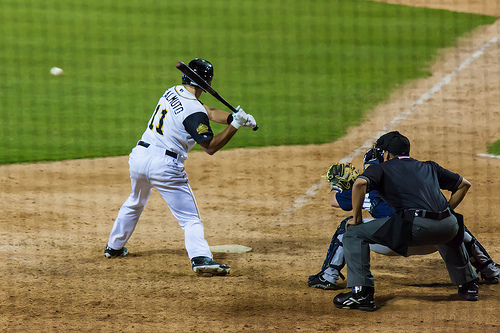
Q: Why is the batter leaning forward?
A: To hit the ball.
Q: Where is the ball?
A: Coming towards the batter.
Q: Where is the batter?
A: At home plate.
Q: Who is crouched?
A: The catcher and the umpire.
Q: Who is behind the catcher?
A: The umpire.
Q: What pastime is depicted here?
A: Baseball.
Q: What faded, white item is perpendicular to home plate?
A: A line.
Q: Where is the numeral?
A: On the back of the player's jersey.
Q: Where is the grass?
A: On the outfield.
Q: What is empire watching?
A: Pitch.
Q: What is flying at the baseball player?
A: A baseball.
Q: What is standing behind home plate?
A: A catcher.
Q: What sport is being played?
A: Baseball.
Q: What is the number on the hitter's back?
A: 11.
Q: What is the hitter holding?
A: A baseball bat.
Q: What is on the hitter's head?
A: A baseball helmet.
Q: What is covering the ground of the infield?
A: Grass.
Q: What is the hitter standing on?
A: Dirt.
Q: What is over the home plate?
A: The hitter.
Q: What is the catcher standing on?
A: Dirt.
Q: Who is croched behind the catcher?
A: The umpire.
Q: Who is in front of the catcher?
A: The batter.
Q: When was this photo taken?
A: During the day.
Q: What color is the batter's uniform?
A: White.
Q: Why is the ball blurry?
A: It is in motion.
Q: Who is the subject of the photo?
A: The players.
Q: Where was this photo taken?
A: On a baseball diamond.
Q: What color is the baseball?
A: White.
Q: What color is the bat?
A: Black.